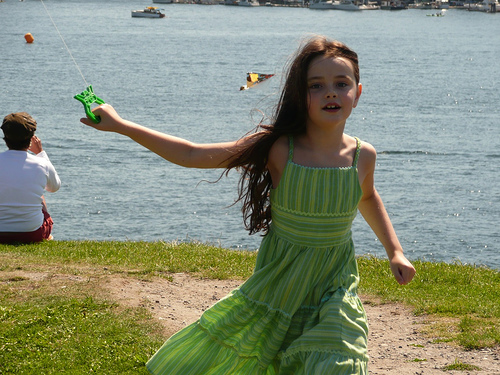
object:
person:
[0, 111, 61, 243]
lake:
[0, 0, 499, 270]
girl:
[78, 34, 414, 375]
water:
[120, 51, 237, 121]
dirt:
[134, 271, 198, 323]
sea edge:
[423, 254, 500, 269]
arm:
[357, 140, 405, 256]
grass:
[440, 266, 480, 290]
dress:
[143, 135, 370, 375]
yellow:
[283, 170, 291, 208]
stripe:
[317, 169, 355, 208]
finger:
[391, 266, 417, 285]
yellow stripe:
[335, 168, 343, 213]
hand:
[388, 252, 417, 285]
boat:
[131, 6, 165, 18]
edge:
[201, 297, 231, 315]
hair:
[196, 33, 359, 237]